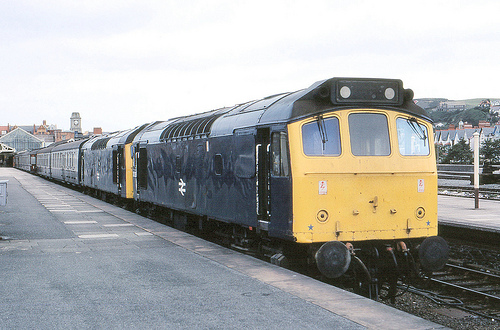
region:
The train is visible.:
[269, 167, 360, 233]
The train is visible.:
[265, 176, 384, 288]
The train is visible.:
[271, 131, 338, 233]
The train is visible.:
[291, 173, 385, 278]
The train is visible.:
[267, 109, 351, 216]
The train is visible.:
[313, 148, 388, 233]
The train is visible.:
[266, 181, 384, 316]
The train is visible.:
[288, 139, 377, 209]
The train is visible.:
[276, 151, 358, 243]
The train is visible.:
[299, 137, 394, 256]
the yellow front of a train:
[281, 110, 433, 246]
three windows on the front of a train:
[303, 119, 428, 166]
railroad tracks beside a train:
[451, 260, 499, 315]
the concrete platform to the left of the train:
[17, 266, 240, 318]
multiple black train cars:
[21, 105, 328, 216]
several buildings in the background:
[4, 115, 79, 137]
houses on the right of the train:
[436, 127, 477, 154]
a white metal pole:
[471, 129, 486, 214]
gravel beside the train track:
[407, 292, 457, 324]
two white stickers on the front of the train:
[313, 173, 428, 198]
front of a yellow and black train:
[264, 79, 429, 251]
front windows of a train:
[306, 116, 437, 163]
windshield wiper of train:
[308, 111, 330, 156]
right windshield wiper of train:
[401, 113, 444, 145]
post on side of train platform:
[459, 131, 490, 219]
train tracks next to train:
[391, 230, 498, 313]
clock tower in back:
[56, 109, 93, 137]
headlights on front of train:
[324, 79, 408, 99]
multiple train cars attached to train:
[13, 100, 137, 205]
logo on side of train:
[153, 161, 208, 209]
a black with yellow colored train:
[7, 72, 459, 286]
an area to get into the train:
[249, 118, 289, 268]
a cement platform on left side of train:
[2, 159, 387, 328]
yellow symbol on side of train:
[171, 173, 187, 199]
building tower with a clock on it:
[63, 103, 88, 137]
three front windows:
[305, 104, 434, 169]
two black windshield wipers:
[295, 105, 440, 152]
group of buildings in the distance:
[5, 98, 116, 167]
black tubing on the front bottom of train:
[339, 228, 425, 305]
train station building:
[7, 122, 50, 172]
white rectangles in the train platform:
[26, 171, 148, 242]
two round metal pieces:
[311, 227, 453, 279]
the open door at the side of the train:
[251, 127, 278, 237]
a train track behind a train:
[448, 178, 498, 198]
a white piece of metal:
[1, 141, 18, 157]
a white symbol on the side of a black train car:
[168, 168, 188, 198]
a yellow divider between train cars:
[121, 144, 138, 196]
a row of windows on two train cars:
[38, 152, 75, 167]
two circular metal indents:
[314, 200, 426, 222]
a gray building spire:
[66, 110, 87, 129]